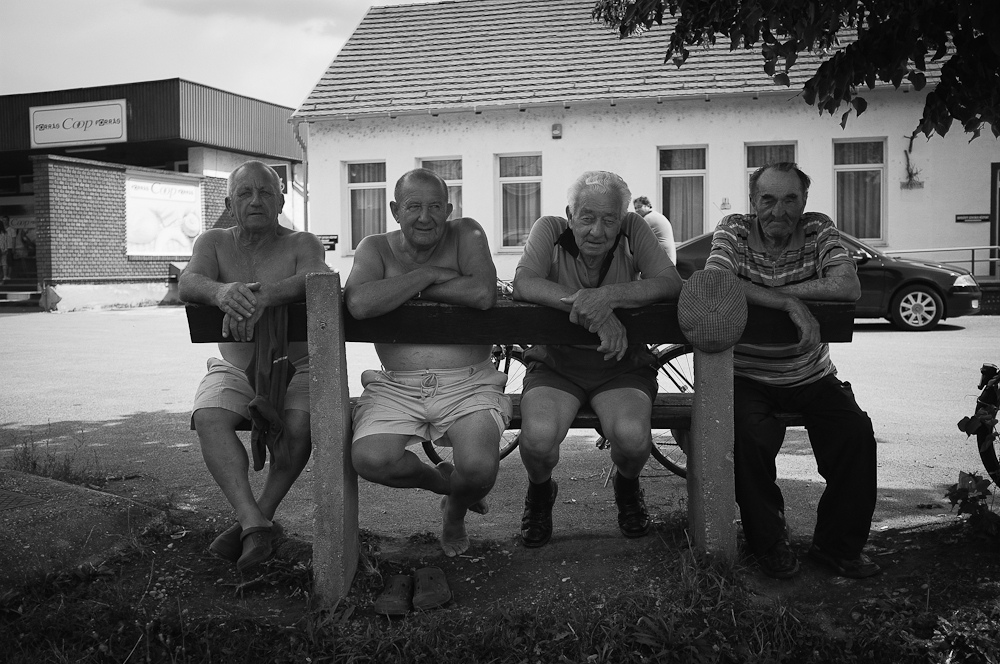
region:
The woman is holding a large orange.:
[311, 457, 358, 511]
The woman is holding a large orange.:
[485, 500, 532, 575]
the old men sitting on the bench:
[177, 160, 878, 582]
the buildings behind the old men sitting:
[0, 1, 998, 581]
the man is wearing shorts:
[347, 166, 515, 556]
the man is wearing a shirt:
[517, 169, 678, 541]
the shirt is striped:
[702, 211, 860, 389]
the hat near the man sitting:
[677, 160, 882, 580]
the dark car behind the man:
[675, 159, 980, 576]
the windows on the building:
[287, 0, 998, 315]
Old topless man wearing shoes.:
[174, 156, 328, 580]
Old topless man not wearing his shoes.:
[345, 165, 515, 559]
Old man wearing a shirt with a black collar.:
[510, 160, 674, 550]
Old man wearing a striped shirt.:
[695, 155, 890, 589]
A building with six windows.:
[287, 0, 997, 320]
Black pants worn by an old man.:
[725, 370, 875, 567]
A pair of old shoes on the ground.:
[370, 562, 455, 612]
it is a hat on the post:
[685, 254, 740, 364]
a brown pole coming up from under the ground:
[293, 257, 377, 602]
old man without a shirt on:
[186, 153, 327, 555]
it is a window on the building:
[495, 150, 550, 250]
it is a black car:
[669, 207, 964, 332]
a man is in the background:
[619, 187, 697, 272]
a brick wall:
[26, 140, 238, 290]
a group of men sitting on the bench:
[172, 160, 882, 591]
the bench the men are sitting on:
[180, 274, 867, 594]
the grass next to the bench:
[35, 571, 847, 661]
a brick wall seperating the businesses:
[32, 147, 233, 311]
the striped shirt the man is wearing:
[702, 203, 864, 385]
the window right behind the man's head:
[740, 131, 798, 183]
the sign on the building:
[20, 103, 137, 150]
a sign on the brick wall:
[116, 170, 210, 260]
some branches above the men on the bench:
[596, 0, 991, 157]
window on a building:
[342, 155, 386, 253]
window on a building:
[425, 145, 457, 203]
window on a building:
[488, 143, 535, 243]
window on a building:
[651, 141, 715, 245]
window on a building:
[822, 133, 882, 243]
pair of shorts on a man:
[183, 355, 307, 465]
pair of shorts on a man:
[365, 367, 533, 458]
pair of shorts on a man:
[511, 335, 669, 422]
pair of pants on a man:
[729, 371, 879, 558]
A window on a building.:
[502, 148, 547, 242]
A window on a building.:
[422, 155, 482, 226]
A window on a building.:
[345, 152, 377, 259]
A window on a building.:
[652, 137, 702, 241]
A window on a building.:
[736, 137, 781, 201]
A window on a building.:
[835, 138, 883, 162]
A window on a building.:
[746, 138, 800, 162]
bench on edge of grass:
[167, 266, 864, 583]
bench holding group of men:
[168, 263, 858, 600]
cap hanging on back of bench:
[673, 261, 761, 356]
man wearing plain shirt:
[505, 198, 672, 382]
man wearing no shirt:
[338, 219, 498, 397]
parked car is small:
[650, 191, 997, 345]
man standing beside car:
[624, 193, 688, 297]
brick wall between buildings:
[18, 152, 270, 337]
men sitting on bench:
[134, 119, 814, 519]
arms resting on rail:
[125, 184, 993, 378]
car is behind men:
[671, 107, 939, 412]